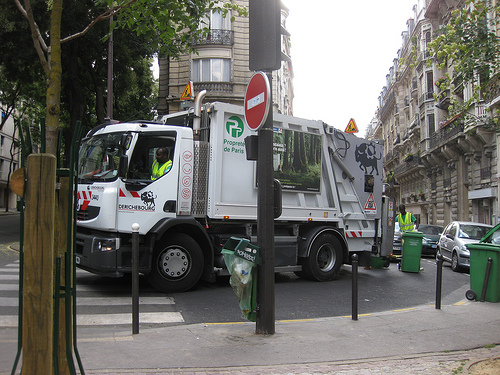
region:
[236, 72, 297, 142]
sign is red and white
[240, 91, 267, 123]
white dash on sign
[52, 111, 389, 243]
bin lorry is white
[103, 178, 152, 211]
red and white stripe on door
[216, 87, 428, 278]
white trash receptacle on truck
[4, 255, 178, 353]
white stripes on street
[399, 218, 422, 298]
green trash bin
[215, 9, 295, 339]
sign on steel post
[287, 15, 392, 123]
sky is grey and overcast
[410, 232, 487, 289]
silver car in street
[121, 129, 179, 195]
the window of a truck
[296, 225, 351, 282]
the wheel of a truck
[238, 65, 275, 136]
a red and white sign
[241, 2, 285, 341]
a black metal pole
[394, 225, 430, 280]
a green waste bin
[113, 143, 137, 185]
a side view mirror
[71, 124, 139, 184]
the windshield of a truck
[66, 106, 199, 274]
the cab of the truck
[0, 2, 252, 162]
a leafy green tree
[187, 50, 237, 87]
a window on the building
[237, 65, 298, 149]
the sign is red and silver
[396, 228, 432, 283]
the trashcan is green in color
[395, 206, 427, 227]
the vest is neon green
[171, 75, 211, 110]
the sign is red yellow and black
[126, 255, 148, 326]
this pole is grey in color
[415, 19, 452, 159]
this building has three windows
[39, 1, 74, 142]
this tree has moss on it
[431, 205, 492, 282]
the car is silver in color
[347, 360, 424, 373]
the sidewalk is partially made of bricks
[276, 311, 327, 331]
the curb has yellow lines on it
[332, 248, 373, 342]
a small black pole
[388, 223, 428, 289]
a tall green garbage can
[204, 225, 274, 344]
doggie bags on a tree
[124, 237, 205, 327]
black tire with gray rim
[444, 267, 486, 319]
black wheel on a trash can bottom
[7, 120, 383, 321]
garbage truckon street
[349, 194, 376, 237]
red and white sign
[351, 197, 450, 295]
man with a trash can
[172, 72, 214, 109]
orange and yellow sign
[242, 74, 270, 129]
A stop sign is on the pole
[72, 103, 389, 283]
A garbage truck on the street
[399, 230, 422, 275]
The garbage can is green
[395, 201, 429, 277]
Garbageman collecting garbage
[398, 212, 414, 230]
The garbageman wears a yellow vest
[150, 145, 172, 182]
Man is driving garbage truck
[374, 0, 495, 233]
Buildings by the street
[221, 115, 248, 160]
Garbage truck is property of Paris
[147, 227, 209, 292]
Garbage truck has large tires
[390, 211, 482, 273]
Vehicles parked on the street